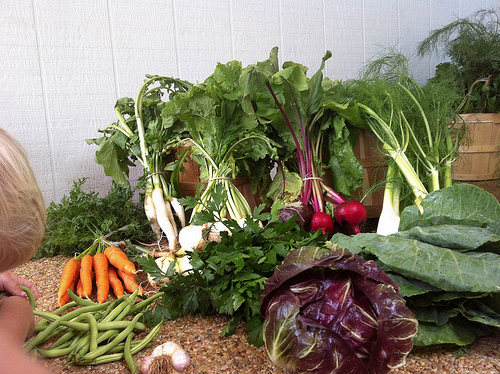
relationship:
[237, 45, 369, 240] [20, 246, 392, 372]
beets on a table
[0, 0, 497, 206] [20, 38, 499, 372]
wall in front of vegetables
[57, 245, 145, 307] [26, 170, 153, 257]
carrot with leaves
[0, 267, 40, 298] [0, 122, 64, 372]
hand of child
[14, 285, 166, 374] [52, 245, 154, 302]
beans of carrots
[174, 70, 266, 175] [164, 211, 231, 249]
tops of onions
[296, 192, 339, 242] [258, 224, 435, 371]
radish next to lettuce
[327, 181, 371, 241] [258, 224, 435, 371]
radish next to lettuce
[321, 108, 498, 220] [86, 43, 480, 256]
barrel on side of greens